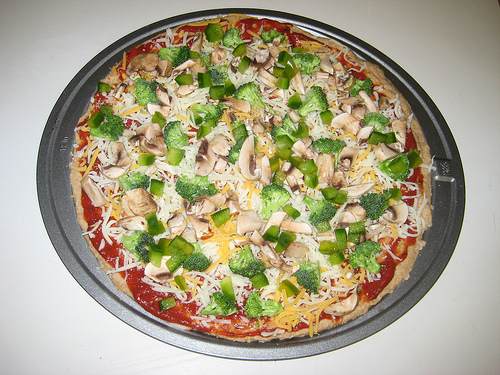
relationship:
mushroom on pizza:
[233, 129, 260, 181] [48, 65, 449, 349]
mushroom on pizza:
[381, 200, 409, 226] [48, 65, 449, 349]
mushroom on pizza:
[127, 124, 169, 159] [48, 65, 449, 349]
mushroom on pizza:
[118, 184, 160, 218] [48, 65, 449, 349]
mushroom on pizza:
[113, 217, 150, 232] [48, 65, 449, 349]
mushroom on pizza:
[385, 119, 412, 147] [48, 65, 449, 349]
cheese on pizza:
[215, 164, 258, 201] [67, 15, 439, 335]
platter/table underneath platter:
[0, 0, 500, 375] [29, 19, 469, 350]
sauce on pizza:
[68, 27, 454, 330] [168, 57, 330, 204]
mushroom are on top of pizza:
[236, 134, 271, 179] [67, 15, 439, 335]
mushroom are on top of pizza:
[261, 210, 309, 234] [67, 15, 439, 335]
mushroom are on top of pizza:
[123, 185, 158, 216] [67, 15, 439, 335]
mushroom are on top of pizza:
[329, 110, 361, 142] [67, 15, 439, 335]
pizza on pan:
[67, 15, 439, 335] [40, 5, 468, 366]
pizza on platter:
[67, 15, 439, 341] [29, 19, 469, 350]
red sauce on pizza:
[109, 47, 275, 320] [67, 15, 439, 341]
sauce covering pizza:
[67, 18, 422, 337] [67, 15, 439, 335]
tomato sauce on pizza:
[72, 17, 423, 341] [67, 15, 439, 335]